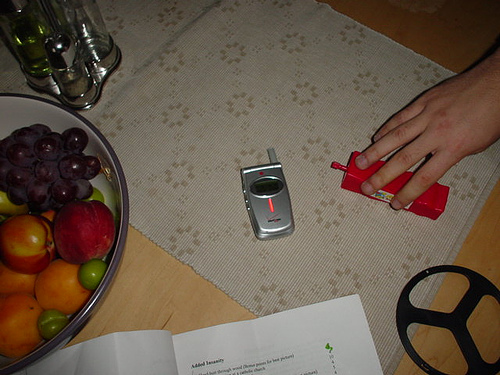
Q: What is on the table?
A: A cell phone.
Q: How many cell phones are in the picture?
A: One.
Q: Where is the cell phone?
A: On a table.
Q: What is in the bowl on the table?
A: Fruit.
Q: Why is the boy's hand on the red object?
A: To retrieve.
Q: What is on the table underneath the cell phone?
A: A tablecloth runner.